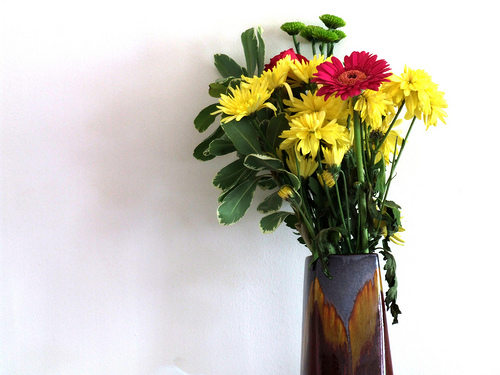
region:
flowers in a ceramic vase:
[134, 25, 457, 374]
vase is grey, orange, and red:
[288, 231, 415, 373]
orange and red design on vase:
[302, 270, 389, 374]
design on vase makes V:
[310, 280, 385, 373]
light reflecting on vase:
[367, 255, 404, 373]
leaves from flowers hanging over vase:
[368, 176, 416, 328]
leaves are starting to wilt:
[373, 171, 425, 325]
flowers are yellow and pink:
[216, 53, 455, 233]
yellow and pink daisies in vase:
[222, 59, 457, 269]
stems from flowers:
[289, 201, 425, 263]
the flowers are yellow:
[189, 0, 451, 374]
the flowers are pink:
[259, 44, 393, 104]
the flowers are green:
[277, 11, 347, 46]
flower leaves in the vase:
[191, 21, 410, 326]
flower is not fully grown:
[275, 186, 299, 202]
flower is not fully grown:
[314, 166, 339, 189]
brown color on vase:
[306, 272, 386, 368]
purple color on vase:
[297, 309, 394, 374]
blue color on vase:
[303, 252, 384, 333]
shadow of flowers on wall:
[42, 37, 274, 372]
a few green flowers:
[272, 9, 361, 60]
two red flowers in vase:
[252, 38, 402, 119]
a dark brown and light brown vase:
[297, 267, 379, 372]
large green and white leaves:
[178, 89, 333, 259]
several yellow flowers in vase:
[232, 59, 441, 189]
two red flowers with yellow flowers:
[197, 33, 450, 256]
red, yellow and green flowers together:
[228, 5, 436, 202]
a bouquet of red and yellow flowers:
[169, 2, 431, 277]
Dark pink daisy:
[311, 48, 393, 99]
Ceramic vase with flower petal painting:
[293, 250, 393, 374]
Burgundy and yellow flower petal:
[300, 276, 350, 373]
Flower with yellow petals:
[397, 63, 447, 132]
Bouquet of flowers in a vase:
[192, 9, 446, 374]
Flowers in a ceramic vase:
[189, 10, 449, 373]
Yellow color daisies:
[218, 51, 445, 198]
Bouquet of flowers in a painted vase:
[193, 10, 448, 373]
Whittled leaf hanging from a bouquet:
[373, 243, 403, 329]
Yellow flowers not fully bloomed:
[277, 168, 339, 205]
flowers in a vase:
[187, 3, 471, 373]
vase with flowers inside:
[299, 253, 394, 372]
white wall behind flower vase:
[31, 95, 121, 326]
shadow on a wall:
[158, 259, 289, 368]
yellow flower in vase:
[396, 59, 437, 135]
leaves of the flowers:
[215, 156, 259, 232]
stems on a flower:
[355, 123, 390, 207]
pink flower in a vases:
[310, 51, 390, 97]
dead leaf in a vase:
[379, 246, 414, 324]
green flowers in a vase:
[281, 4, 348, 47]